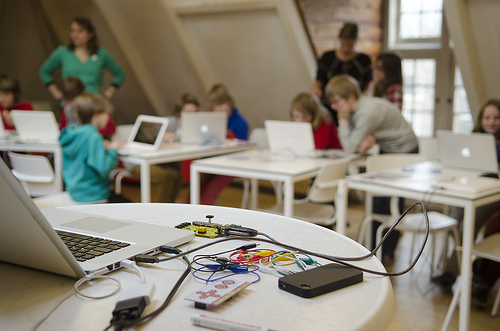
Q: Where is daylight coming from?
A: Windows.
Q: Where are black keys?
A: On laptop computer.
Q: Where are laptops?
A: On the tables.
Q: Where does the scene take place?
A: In a classroom.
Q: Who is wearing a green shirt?
A: Woman standing up.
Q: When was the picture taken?
A: During the daytime.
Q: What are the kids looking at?
A: Laptop screens.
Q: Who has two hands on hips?
A: Woman in green.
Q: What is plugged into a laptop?
A: Electric wires.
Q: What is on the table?
A: A laptop.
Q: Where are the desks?
A: In the room.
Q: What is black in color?
A: The phone.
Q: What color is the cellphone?
A: Black.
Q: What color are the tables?
A: White.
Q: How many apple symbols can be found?
A: Two.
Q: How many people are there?
A: Eleven.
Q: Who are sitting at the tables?
A: Children.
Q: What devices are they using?
A: Laptops.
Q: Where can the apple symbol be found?
A: On the laptop.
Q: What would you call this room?
A: A class room.